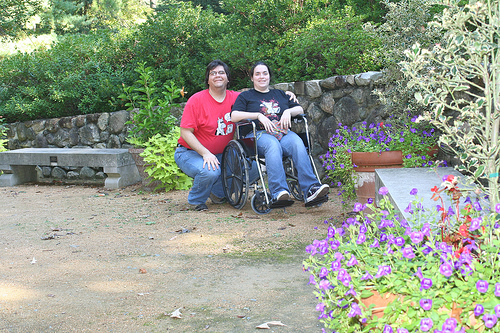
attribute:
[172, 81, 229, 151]
shirt — red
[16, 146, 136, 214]
bench — gray, stone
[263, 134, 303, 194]
jeans — blue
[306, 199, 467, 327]
flowers — purple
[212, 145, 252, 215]
wheel — round, black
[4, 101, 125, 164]
wall — long, stone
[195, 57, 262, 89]
hair — dark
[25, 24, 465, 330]
area — outdoor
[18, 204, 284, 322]
backyard — dirt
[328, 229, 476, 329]
flowers — purple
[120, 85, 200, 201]
bush — tall, green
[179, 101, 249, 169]
shirt — red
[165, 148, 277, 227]
jeans — blue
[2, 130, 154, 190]
bench — concrete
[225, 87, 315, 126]
shirt — black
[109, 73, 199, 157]
plants — green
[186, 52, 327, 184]
woman — sitting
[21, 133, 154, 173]
bench — stone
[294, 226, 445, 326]
flowers — purple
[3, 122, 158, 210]
bench — concrete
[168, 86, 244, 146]
t-shirt — red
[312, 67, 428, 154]
wall — rock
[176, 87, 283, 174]
shirt — red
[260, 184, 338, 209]
shoes — pair, black, white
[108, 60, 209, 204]
leaves — green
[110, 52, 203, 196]
leaves — green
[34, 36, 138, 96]
leaves — green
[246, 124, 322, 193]
jeans — blue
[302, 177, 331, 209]
shoe — black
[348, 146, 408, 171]
brick — brown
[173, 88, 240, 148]
short — red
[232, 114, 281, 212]
wheelchair — metal framed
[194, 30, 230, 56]
leaves — green